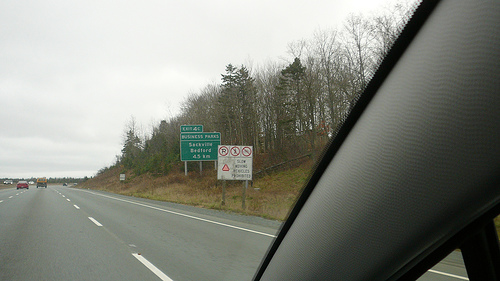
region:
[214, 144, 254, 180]
white street sign on a double post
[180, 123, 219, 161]
a green sign on three posts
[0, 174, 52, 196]
traffic on the highway ahead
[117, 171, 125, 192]
a small sign on the right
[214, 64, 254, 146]
evergreen trees on the hillside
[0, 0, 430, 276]
the windshield of a vehicle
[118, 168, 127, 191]
speed limit sign on the highway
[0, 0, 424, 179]
a completely cloudy sky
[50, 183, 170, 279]
white lines for lane demarkation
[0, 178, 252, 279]
a three lane highway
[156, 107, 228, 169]
A green sign on the side of highway.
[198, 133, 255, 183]
White sign on the highway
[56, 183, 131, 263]
White lines in the road.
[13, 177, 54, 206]
Cars driving on the highway.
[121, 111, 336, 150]
Trees on the side of the highway.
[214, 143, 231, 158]
No parking on the white sign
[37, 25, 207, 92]
The sky is cloudy.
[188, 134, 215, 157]
The green sign is white letters.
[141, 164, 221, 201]
Grass on the hill.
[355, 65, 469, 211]
The side of the inside of a car.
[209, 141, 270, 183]
red and white street sign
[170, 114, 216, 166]
green and white sign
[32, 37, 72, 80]
white clouds in blue sky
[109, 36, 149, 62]
white clouds in blue sky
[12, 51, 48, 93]
white clouds in blue sky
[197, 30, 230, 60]
white clouds in blue sky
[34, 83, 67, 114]
white clouds in blue sky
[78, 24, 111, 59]
white clouds in blue sky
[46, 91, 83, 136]
white clouds in blue sky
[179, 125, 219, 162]
a green sign on the side of the road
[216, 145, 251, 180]
a white sign on the side of the road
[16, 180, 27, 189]
a car driving down the street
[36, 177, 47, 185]
a truck driving down the street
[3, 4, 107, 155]
clouds in the sky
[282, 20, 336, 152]
trees on the side of the road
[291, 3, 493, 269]
part of the inside of the car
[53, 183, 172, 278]
white lines on the road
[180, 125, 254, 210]
signs on the side of the road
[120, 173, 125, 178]
a speed limit sign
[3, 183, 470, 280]
The road in front of the car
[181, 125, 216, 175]
A green sign on the side of the road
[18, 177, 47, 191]
Vehicles on the road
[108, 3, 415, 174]
Trees on the side of the road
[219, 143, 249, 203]
A white sign on the side of the road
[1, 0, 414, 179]
The sky above the road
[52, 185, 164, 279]
White traffic lines on the road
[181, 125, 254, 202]
Signs near the road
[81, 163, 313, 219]
Grass next to the road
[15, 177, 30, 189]
A vehicle driving near the trees